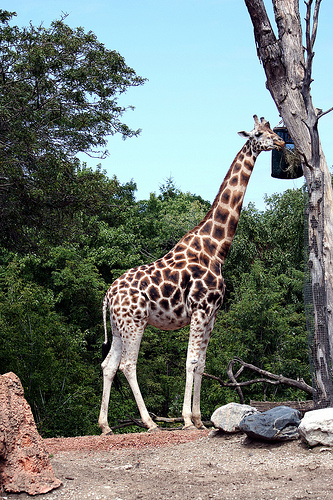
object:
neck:
[198, 143, 257, 266]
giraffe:
[93, 114, 286, 437]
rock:
[297, 404, 332, 450]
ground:
[0, 427, 332, 499]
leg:
[190, 308, 216, 430]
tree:
[243, 0, 332, 410]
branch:
[243, 0, 280, 78]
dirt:
[94, 433, 179, 458]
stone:
[209, 400, 260, 435]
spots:
[201, 234, 218, 258]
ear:
[235, 128, 254, 142]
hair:
[253, 121, 279, 140]